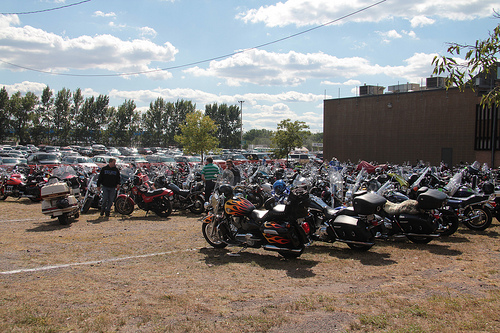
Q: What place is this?
A: It is a field.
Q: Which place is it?
A: It is a field.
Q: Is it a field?
A: Yes, it is a field.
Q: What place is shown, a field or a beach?
A: It is a field.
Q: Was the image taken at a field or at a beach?
A: It was taken at a field.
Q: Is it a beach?
A: No, it is a field.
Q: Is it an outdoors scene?
A: Yes, it is outdoors.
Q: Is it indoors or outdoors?
A: It is outdoors.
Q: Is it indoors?
A: No, it is outdoors.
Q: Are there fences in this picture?
A: No, there are no fences.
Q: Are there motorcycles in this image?
A: Yes, there is a motorcycle.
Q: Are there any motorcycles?
A: Yes, there is a motorcycle.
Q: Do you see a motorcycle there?
A: Yes, there is a motorcycle.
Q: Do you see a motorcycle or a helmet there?
A: Yes, there is a motorcycle.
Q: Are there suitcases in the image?
A: No, there are no suitcases.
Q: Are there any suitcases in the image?
A: No, there are no suitcases.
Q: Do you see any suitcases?
A: No, there are no suitcases.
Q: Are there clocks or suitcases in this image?
A: No, there are no suitcases or clocks.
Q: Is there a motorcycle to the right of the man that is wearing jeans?
A: Yes, there is a motorcycle to the right of the man.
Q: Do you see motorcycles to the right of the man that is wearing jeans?
A: Yes, there is a motorcycle to the right of the man.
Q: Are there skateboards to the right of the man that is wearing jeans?
A: No, there is a motorcycle to the right of the man.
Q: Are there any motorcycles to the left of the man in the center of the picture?
A: Yes, there is a motorcycle to the left of the man.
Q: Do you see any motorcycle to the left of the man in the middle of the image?
A: Yes, there is a motorcycle to the left of the man.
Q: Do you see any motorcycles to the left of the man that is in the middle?
A: Yes, there is a motorcycle to the left of the man.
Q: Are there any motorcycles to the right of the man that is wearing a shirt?
A: No, the motorcycle is to the left of the man.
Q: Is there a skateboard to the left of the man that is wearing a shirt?
A: No, there is a motorcycle to the left of the man.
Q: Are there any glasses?
A: No, there are no glasses.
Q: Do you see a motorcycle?
A: Yes, there is a motorcycle.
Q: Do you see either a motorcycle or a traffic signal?
A: Yes, there is a motorcycle.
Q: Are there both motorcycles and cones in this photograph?
A: No, there is a motorcycle but no cones.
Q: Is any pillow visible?
A: No, there are no pillows.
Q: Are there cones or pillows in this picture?
A: No, there are no pillows or cones.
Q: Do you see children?
A: No, there are no children.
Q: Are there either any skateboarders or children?
A: No, there are no children or skateboarders.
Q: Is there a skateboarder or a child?
A: No, there are no children or skateboarders.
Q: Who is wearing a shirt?
A: The man is wearing a shirt.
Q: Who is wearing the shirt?
A: The man is wearing a shirt.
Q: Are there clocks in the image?
A: No, there are no clocks.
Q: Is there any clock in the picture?
A: No, there are no clocks.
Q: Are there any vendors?
A: No, there are no vendors.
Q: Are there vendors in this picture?
A: No, there are no vendors.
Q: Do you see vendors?
A: No, there are no vendors.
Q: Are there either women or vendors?
A: No, there are no vendors or women.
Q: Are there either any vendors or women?
A: No, there are no vendors or women.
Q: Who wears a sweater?
A: The man wears a sweater.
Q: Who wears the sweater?
A: The man wears a sweater.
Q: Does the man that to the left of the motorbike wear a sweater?
A: Yes, the man wears a sweater.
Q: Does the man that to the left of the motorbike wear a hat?
A: No, the man wears a sweater.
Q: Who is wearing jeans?
A: The man is wearing jeans.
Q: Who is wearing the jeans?
A: The man is wearing jeans.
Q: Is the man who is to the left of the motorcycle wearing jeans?
A: Yes, the man is wearing jeans.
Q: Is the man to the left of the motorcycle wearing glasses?
A: No, the man is wearing jeans.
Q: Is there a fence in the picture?
A: No, there are no fences.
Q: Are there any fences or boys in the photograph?
A: No, there are no fences or boys.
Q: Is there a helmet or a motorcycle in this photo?
A: Yes, there is a motorcycle.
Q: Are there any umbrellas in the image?
A: No, there are no umbrellas.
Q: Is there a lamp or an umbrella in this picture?
A: No, there are no umbrellas or lamps.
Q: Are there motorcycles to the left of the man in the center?
A: Yes, there is a motorcycle to the left of the man.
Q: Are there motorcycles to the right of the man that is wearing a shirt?
A: No, the motorcycle is to the left of the man.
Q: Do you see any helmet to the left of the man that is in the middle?
A: No, there is a motorcycle to the left of the man.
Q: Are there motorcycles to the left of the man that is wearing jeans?
A: Yes, there is a motorcycle to the left of the man.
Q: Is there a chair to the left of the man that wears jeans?
A: No, there is a motorcycle to the left of the man.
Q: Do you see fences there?
A: No, there are no fences.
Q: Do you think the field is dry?
A: Yes, the field is dry.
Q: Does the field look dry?
A: Yes, the field is dry.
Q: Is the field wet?
A: No, the field is dry.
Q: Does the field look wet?
A: No, the field is dry.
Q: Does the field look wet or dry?
A: The field is dry.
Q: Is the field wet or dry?
A: The field is dry.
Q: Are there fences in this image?
A: No, there are no fences.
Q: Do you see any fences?
A: No, there are no fences.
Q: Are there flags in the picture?
A: No, there are no flags.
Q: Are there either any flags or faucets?
A: No, there are no flags or faucets.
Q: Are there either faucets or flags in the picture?
A: No, there are no flags or faucets.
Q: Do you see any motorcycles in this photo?
A: Yes, there is a motorcycle.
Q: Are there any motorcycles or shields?
A: Yes, there is a motorcycle.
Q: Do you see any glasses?
A: No, there are no glasses.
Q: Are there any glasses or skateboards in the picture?
A: No, there are no glasses or skateboards.